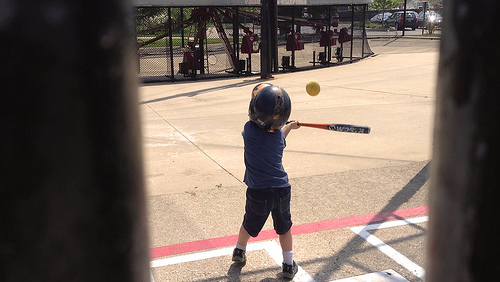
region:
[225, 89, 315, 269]
THAT IS A CHILD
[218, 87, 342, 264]
THE CHILD IS PLAYING BASEBALL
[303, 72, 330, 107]
THAT IS A BALL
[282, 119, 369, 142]
THAT IS A BASEBALL BAT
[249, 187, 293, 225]
THE CHILD IS WEARING BLACK SHORTS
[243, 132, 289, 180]
THAT CHILD IS WEARING BLUE T SHIRT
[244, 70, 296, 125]
THAT IS A HELMNET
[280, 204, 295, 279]
THAT IS A LEG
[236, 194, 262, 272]
THAT IS A LEG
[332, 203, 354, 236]
MARKING ON THEGROUND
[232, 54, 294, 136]
boy has black helmet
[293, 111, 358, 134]
red and black bat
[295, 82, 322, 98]
large yellow baseball near boy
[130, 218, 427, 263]
red line on ground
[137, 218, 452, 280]
white lines for batter's box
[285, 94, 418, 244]
concrete is light brown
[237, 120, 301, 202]
boy has blue shirt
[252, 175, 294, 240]
boy has black shorts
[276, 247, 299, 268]
boy has white socks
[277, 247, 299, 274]
black and white shoes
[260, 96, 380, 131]
red and black bat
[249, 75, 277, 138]
boy has blue helmet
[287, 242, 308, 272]
boy has white socks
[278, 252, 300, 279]
boy has black shoes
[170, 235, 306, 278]
white lines on batter's box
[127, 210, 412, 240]
red line on sidewalk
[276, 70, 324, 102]
ball is large and yellow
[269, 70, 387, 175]
sidewalk is light brown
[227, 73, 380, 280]
little boy at a batting cage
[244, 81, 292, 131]
black and orange base ball helmet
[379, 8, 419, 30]
a black parked vehicle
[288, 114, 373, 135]
orange and black base ball bat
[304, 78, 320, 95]
yellow base ball in motion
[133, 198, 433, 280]
red and white lines painted on the ground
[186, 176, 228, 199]
plants growing through cracks in the ground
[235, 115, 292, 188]
navy blue tee shirt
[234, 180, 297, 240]
dark blue denim shorts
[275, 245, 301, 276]
white socks and black shoes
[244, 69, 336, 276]
The child is holding a bat.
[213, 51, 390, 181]
The child is hitting the ball.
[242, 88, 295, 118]
The child is wearing a helmet.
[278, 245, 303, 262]
The child has on white socks.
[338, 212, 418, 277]
White lines on the court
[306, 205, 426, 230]
A red line on the court.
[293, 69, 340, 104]
The ball is in the air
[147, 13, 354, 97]
A fence around the court.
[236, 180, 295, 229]
The child is wearing jean shorts.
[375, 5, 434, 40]
Cars parked in the parking lot.